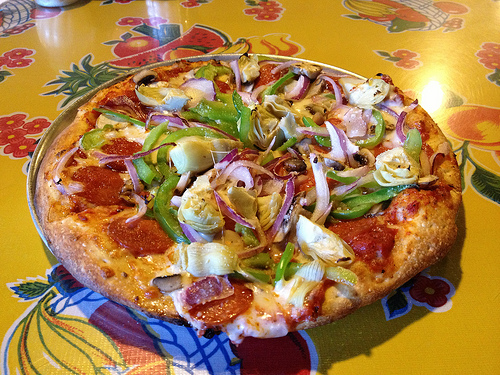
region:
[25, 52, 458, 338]
Gourmet pizza with several toppings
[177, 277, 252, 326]
Slice of pepperoni on a pizza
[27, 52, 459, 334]
Pizza topped with onion, peppers, and pepperoni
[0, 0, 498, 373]
Pizza pie sititing on a table with a colorful tablecloth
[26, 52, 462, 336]
Pizza with many toppings sitting on a metal pizza plate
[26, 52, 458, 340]
Pepperoni pizza with cheese, peppers, and roasted garlic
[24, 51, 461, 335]
Thin crust pizza with heavy toppings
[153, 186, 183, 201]
green peppers on the pizza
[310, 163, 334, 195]
onions on the pizza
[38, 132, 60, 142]
a silver plate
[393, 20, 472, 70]
a table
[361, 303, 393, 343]
a shadow under the pizza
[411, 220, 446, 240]
the crust is brown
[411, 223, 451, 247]
brown crust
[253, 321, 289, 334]
cheese on the pizza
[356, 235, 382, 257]
the sauce is red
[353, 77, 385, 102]
mushrooms on the pizza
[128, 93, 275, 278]
green peppers on pizza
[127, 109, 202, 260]
green peppers on pizza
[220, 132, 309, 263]
onions on the pizza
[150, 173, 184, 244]
green pepper on pizza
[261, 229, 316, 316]
green pepper on pizza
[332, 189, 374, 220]
green pepper on pizza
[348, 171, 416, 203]
green pepper on pizza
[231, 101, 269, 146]
green pepper on pizza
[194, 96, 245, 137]
green pepper on pizza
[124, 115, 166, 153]
green pepper on pizza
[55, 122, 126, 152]
green pepper on pizza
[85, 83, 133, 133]
green pepper on pizza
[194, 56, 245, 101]
green pepper on pizza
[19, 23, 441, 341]
small round pizza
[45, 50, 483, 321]
pizza with thick crust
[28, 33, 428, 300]
pizza with slices of pepperoni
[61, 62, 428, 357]
pizza with artichoke slices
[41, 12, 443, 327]
pizza with red onions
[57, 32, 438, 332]
pizza with white onions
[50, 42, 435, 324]
pizza with green bell pepper slices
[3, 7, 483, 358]
yellow tablecloth with flowers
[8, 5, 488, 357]
yellow tablecloth with fruit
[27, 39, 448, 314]
pizza on pizza pan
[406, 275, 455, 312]
flower painted on table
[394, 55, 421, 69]
flower painted on table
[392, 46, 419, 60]
flower painted on table